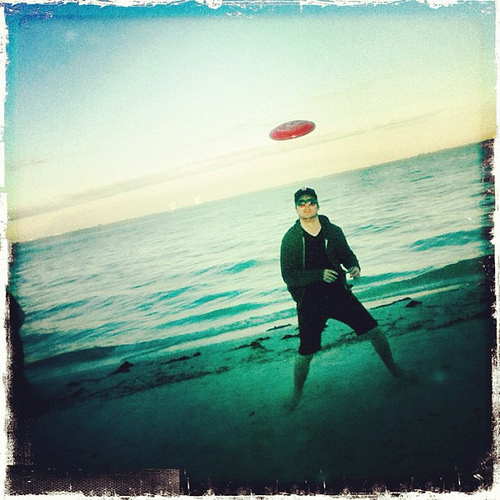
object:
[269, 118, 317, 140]
freesbee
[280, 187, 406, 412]
man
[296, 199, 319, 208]
sunglasses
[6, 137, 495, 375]
water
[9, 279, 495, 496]
sand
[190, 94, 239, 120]
air